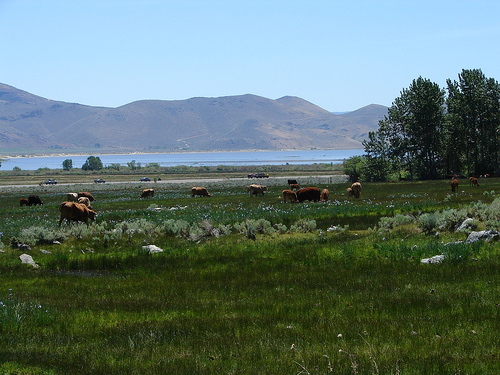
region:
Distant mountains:
[1, 77, 412, 154]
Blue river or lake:
[1, 148, 414, 170]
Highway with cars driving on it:
[0, 170, 456, 188]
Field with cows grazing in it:
[3, 179, 494, 369]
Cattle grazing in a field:
[246, 177, 365, 209]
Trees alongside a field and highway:
[328, 66, 498, 186]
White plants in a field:
[17, 214, 335, 242]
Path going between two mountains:
[158, 124, 226, 154]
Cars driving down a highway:
[36, 167, 160, 189]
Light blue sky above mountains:
[3, 4, 497, 125]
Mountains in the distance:
[4, 77, 416, 152]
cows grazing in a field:
[14, 175, 491, 284]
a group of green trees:
[327, 62, 495, 187]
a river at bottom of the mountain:
[4, 135, 386, 174]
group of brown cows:
[49, 178, 373, 224]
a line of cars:
[9, 164, 342, 186]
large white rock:
[15, 250, 47, 277]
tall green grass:
[70, 224, 473, 366]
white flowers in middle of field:
[9, 222, 221, 249]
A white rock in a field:
[399, 236, 453, 273]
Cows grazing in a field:
[45, 177, 115, 239]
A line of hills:
[11, 57, 328, 153]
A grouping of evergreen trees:
[347, 52, 499, 177]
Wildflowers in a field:
[274, 321, 369, 373]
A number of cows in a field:
[53, 160, 387, 225]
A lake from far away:
[128, 136, 367, 173]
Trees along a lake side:
[55, 152, 154, 174]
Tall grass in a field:
[181, 272, 278, 330]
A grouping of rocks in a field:
[418, 198, 495, 295]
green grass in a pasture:
[109, 221, 416, 346]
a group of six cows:
[13, 172, 103, 232]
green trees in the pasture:
[343, 71, 495, 188]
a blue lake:
[79, 142, 351, 171]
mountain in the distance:
[6, 77, 343, 153]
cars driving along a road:
[6, 167, 328, 189]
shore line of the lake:
[9, 144, 327, 161]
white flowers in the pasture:
[198, 199, 285, 219]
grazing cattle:
[271, 171, 333, 209]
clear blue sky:
[31, 5, 428, 129]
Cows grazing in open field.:
[55, 181, 379, 249]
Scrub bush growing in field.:
[18, 218, 301, 244]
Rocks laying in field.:
[422, 211, 496, 289]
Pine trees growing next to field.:
[376, 81, 498, 178]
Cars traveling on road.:
[5, 167, 341, 187]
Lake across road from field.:
[3, 139, 393, 171]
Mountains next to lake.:
[3, 85, 383, 158]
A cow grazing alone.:
[464, 172, 489, 198]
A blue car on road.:
[132, 170, 163, 186]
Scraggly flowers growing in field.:
[283, 320, 400, 373]